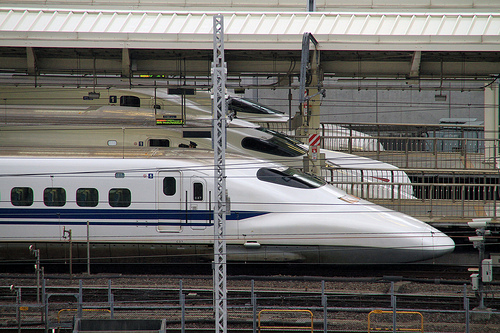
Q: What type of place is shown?
A: It is a train station.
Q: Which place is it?
A: It is a train station.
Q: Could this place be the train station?
A: Yes, it is the train station.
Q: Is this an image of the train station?
A: Yes, it is showing the train station.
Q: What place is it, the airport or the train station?
A: It is the train station.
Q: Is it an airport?
A: No, it is a train station.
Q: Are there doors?
A: Yes, there is a door.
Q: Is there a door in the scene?
A: Yes, there is a door.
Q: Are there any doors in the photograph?
A: Yes, there is a door.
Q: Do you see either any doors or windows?
A: Yes, there is a door.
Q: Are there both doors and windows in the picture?
A: Yes, there are both a door and a window.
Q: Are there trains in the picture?
A: Yes, there are trains.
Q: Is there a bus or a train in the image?
A: Yes, there are trains.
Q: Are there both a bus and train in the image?
A: No, there are trains but no buses.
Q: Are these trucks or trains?
A: These are trains.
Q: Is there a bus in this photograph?
A: No, there are no buses.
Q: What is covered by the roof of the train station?
A: The building is covered by the roof.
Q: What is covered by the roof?
A: The building is covered by the roof.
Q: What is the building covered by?
A: The building is covered by the roof.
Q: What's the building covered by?
A: The building is covered by the roof.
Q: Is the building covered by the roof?
A: Yes, the building is covered by the roof.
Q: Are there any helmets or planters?
A: No, there are no helmets or planters.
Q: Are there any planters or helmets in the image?
A: No, there are no helmets or planters.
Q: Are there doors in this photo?
A: Yes, there is a door.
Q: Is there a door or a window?
A: Yes, there is a door.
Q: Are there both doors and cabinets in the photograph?
A: No, there is a door but no cabinets.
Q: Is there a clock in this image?
A: No, there are no clocks.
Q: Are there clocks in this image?
A: No, there are no clocks.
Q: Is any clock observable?
A: No, there are no clocks.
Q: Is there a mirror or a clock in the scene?
A: No, there are no clocks or mirrors.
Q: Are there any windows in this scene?
A: Yes, there is a window.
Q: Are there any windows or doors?
A: Yes, there is a window.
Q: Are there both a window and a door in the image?
A: Yes, there are both a window and a door.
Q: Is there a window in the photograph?
A: Yes, there is a window.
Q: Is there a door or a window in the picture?
A: Yes, there is a window.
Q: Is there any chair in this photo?
A: No, there are no chairs.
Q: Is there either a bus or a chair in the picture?
A: No, there are no chairs or buses.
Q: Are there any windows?
A: Yes, there is a window.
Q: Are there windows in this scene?
A: Yes, there is a window.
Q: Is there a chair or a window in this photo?
A: Yes, there is a window.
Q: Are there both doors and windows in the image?
A: Yes, there are both a window and doors.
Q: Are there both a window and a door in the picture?
A: Yes, there are both a window and a door.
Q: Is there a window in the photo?
A: Yes, there is a window.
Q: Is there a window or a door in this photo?
A: Yes, there is a window.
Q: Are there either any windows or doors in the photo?
A: Yes, there is a window.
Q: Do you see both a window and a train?
A: Yes, there are both a window and a train.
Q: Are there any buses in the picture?
A: No, there are no buses.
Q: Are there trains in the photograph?
A: Yes, there is a train.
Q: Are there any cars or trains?
A: Yes, there is a train.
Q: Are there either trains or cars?
A: Yes, there is a train.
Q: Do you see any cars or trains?
A: Yes, there is a train.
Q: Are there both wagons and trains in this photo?
A: No, there is a train but no wagons.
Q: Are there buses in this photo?
A: No, there are no buses.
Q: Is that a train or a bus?
A: That is a train.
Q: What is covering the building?
A: The roof is covering the building.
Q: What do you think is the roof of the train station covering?
A: The roof is covering the building.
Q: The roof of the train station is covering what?
A: The roof is covering the building.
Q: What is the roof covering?
A: The roof is covering the building.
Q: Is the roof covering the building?
A: Yes, the roof is covering the building.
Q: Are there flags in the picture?
A: No, there are no flags.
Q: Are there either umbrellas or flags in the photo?
A: No, there are no flags or umbrellas.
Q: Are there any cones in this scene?
A: No, there are no cones.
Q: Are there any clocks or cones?
A: No, there are no cones or clocks.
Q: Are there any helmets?
A: No, there are no helmets.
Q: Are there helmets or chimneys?
A: No, there are no helmets or chimneys.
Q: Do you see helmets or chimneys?
A: No, there are no helmets or chimneys.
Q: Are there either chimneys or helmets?
A: No, there are no helmets or chimneys.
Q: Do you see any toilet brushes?
A: No, there are no toilet brushes.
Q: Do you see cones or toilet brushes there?
A: No, there are no toilet brushes or cones.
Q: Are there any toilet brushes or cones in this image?
A: No, there are no toilet brushes or cones.